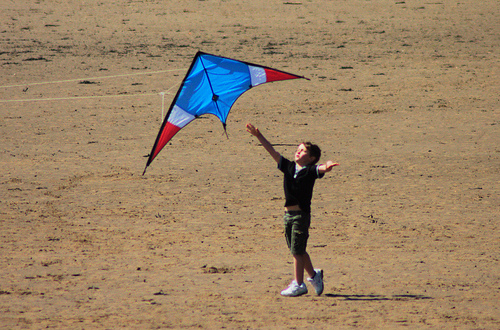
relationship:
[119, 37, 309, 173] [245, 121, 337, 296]
kite above kid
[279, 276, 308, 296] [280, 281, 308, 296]
foot on shoe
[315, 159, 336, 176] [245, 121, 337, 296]
arm of kid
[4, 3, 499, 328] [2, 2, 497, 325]
dirt on ground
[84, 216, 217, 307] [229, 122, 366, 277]
dirt near kid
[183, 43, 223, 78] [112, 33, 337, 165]
part of kite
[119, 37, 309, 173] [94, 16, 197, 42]
kite in air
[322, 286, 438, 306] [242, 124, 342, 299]
shadow behind boy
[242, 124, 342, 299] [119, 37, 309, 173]
boy flying kite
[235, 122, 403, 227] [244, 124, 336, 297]
kid under kite